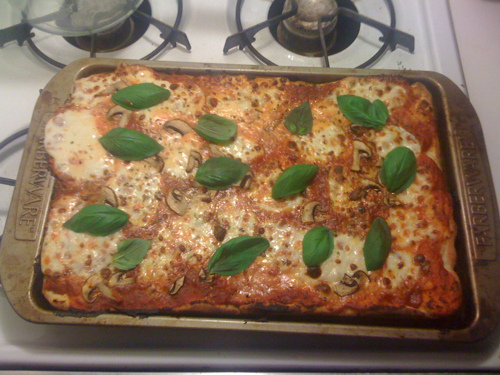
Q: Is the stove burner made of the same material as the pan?
A: Yes, both the stove burner and the pan are made of metal.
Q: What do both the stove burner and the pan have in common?
A: The material, both the stove burner and the pan are metallic.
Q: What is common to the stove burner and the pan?
A: The material, both the stove burner and the pan are metallic.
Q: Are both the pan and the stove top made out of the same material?
A: Yes, both the pan and the stove top are made of metal.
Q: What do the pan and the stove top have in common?
A: The material, both the pan and the stove top are metallic.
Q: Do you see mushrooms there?
A: Yes, there are mushrooms.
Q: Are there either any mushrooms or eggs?
A: Yes, there are mushrooms.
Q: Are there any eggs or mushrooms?
A: Yes, there are mushrooms.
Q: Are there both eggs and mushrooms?
A: No, there are mushrooms but no eggs.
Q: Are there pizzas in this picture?
A: Yes, there is a pizza.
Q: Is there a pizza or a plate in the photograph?
A: Yes, there is a pizza.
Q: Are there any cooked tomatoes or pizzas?
A: Yes, there is a cooked pizza.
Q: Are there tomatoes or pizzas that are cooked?
A: Yes, the pizza is cooked.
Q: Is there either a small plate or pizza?
A: Yes, there is a small pizza.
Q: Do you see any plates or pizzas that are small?
A: Yes, the pizza is small.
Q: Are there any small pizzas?
A: Yes, there is a small pizza.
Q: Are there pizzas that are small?
A: Yes, there is a pizza that is small.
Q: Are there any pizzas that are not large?
A: Yes, there is a small pizza.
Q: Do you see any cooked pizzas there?
A: Yes, there is a cooked pizza.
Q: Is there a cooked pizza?
A: Yes, there is a cooked pizza.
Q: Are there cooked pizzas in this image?
A: Yes, there is a cooked pizza.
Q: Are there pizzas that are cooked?
A: Yes, there is a pizza that is cooked.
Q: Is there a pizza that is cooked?
A: Yes, there is a pizza that is cooked.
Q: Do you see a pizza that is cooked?
A: Yes, there is a pizza that is cooked.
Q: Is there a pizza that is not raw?
A: Yes, there is a cooked pizza.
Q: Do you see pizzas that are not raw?
A: Yes, there is a cooked pizza.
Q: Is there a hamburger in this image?
A: No, there are no hamburgers.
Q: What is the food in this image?
A: The food is a pizza.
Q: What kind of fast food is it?
A: The food is a pizza.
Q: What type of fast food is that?
A: That is a pizza.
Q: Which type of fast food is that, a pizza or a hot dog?
A: That is a pizza.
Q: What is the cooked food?
A: The food is a pizza.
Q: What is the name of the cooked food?
A: The food is a pizza.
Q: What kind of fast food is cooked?
A: The fast food is a pizza.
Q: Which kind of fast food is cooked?
A: The fast food is a pizza.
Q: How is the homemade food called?
A: The food is a pizza.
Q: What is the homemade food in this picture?
A: The food is a pizza.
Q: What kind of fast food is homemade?
A: The fast food is a pizza.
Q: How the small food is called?
A: The food is a pizza.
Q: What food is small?
A: The food is a pizza.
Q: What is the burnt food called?
A: The food is a pizza.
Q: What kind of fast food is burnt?
A: The fast food is a pizza.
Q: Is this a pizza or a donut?
A: This is a pizza.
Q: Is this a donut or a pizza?
A: This is a pizza.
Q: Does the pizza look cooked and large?
A: No, the pizza is cooked but small.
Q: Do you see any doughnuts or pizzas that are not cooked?
A: No, there is a pizza but it is cooked.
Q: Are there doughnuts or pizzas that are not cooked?
A: No, there is a pizza but it is cooked.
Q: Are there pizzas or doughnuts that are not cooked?
A: No, there is a pizza but it is cooked.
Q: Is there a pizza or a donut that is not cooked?
A: No, there is a pizza but it is cooked.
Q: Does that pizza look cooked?
A: Yes, the pizza is cooked.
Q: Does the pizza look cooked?
A: Yes, the pizza is cooked.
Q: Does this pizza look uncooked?
A: No, the pizza is cooked.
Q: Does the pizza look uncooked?
A: No, the pizza is cooked.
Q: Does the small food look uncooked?
A: No, the pizza is cooked.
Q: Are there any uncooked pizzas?
A: No, there is a pizza but it is cooked.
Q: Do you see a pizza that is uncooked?
A: No, there is a pizza but it is cooked.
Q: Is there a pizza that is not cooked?
A: No, there is a pizza but it is cooked.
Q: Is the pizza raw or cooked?
A: The pizza is cooked.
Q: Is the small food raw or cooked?
A: The pizza is cooked.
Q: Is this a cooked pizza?
A: Yes, this is a cooked pizza.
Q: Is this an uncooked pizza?
A: No, this is a cooked pizza.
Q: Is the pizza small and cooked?
A: Yes, the pizza is small and cooked.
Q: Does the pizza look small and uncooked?
A: No, the pizza is small but cooked.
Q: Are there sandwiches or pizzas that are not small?
A: No, there is a pizza but it is small.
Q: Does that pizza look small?
A: Yes, the pizza is small.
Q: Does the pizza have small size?
A: Yes, the pizza is small.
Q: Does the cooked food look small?
A: Yes, the pizza is small.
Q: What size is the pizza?
A: The pizza is small.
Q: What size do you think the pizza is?
A: The pizza is small.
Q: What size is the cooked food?
A: The pizza is small.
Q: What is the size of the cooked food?
A: The pizza is small.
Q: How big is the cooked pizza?
A: The pizza is small.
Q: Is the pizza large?
A: No, the pizza is small.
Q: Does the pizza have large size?
A: No, the pizza is small.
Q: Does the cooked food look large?
A: No, the pizza is small.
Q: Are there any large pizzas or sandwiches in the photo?
A: No, there is a pizza but it is small.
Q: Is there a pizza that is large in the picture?
A: No, there is a pizza but it is small.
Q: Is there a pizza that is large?
A: No, there is a pizza but it is small.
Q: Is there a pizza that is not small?
A: No, there is a pizza but it is small.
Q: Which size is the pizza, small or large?
A: The pizza is small.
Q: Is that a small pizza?
A: Yes, that is a small pizza.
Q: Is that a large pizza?
A: No, that is a small pizza.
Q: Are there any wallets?
A: No, there are no wallets.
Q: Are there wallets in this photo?
A: No, there are no wallets.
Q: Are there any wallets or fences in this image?
A: No, there are no wallets or fences.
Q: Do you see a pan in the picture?
A: Yes, there is a pan.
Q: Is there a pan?
A: Yes, there is a pan.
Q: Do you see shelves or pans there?
A: Yes, there is a pan.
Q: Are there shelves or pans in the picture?
A: Yes, there is a pan.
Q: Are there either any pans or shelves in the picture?
A: Yes, there is a pan.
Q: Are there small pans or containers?
A: Yes, there is a small pan.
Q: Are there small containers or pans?
A: Yes, there is a small pan.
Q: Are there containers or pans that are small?
A: Yes, the pan is small.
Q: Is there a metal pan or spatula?
A: Yes, there is a metal pan.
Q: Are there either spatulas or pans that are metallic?
A: Yes, the pan is metallic.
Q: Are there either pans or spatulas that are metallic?
A: Yes, the pan is metallic.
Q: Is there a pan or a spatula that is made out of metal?
A: Yes, the pan is made of metal.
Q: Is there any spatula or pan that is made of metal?
A: Yes, the pan is made of metal.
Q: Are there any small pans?
A: Yes, there is a small pan.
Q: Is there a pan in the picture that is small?
A: Yes, there is a pan that is small.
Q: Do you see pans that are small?
A: Yes, there is a pan that is small.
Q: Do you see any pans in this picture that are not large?
A: Yes, there is a small pan.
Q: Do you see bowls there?
A: No, there are no bowls.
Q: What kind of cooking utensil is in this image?
A: The cooking utensil is a pan.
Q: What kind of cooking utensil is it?
A: The cooking utensil is a pan.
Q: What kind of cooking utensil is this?
A: That is a pan.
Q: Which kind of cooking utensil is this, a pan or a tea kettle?
A: That is a pan.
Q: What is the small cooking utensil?
A: The cooking utensil is a pan.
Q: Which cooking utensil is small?
A: The cooking utensil is a pan.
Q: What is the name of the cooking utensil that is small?
A: The cooking utensil is a pan.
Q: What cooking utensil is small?
A: The cooking utensil is a pan.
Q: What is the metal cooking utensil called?
A: The cooking utensil is a pan.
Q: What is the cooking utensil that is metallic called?
A: The cooking utensil is a pan.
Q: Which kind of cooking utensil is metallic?
A: The cooking utensil is a pan.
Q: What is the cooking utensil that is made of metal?
A: The cooking utensil is a pan.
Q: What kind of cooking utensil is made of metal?
A: The cooking utensil is a pan.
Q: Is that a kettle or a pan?
A: That is a pan.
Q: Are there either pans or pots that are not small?
A: No, there is a pan but it is small.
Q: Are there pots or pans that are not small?
A: No, there is a pan but it is small.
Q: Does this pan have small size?
A: Yes, the pan is small.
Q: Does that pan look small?
A: Yes, the pan is small.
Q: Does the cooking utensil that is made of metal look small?
A: Yes, the pan is small.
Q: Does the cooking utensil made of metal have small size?
A: Yes, the pan is small.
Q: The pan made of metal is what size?
A: The pan is small.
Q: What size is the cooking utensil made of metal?
A: The pan is small.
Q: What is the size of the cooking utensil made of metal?
A: The pan is small.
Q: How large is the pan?
A: The pan is small.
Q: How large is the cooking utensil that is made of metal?
A: The pan is small.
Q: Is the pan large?
A: No, the pan is small.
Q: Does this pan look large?
A: No, the pan is small.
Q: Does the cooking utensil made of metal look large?
A: No, the pan is small.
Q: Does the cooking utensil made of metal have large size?
A: No, the pan is small.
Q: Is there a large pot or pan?
A: No, there is a pan but it is small.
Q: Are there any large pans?
A: No, there is a pan but it is small.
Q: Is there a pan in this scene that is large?
A: No, there is a pan but it is small.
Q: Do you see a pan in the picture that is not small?
A: No, there is a pan but it is small.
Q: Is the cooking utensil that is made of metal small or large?
A: The pan is small.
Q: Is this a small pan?
A: Yes, this is a small pan.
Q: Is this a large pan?
A: No, this is a small pan.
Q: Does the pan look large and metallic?
A: No, the pan is metallic but small.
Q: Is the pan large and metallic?
A: No, the pan is metallic but small.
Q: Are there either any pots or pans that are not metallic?
A: No, there is a pan but it is metallic.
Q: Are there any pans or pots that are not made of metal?
A: No, there is a pan but it is made of metal.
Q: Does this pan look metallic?
A: Yes, the pan is metallic.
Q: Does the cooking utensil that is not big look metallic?
A: Yes, the pan is metallic.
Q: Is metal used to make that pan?
A: Yes, the pan is made of metal.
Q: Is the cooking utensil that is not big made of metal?
A: Yes, the pan is made of metal.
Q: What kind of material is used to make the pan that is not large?
A: The pan is made of metal.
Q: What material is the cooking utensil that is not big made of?
A: The pan is made of metal.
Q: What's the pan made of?
A: The pan is made of metal.